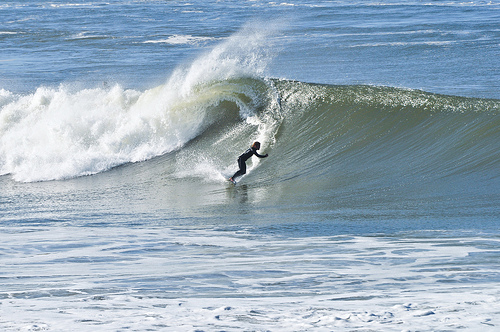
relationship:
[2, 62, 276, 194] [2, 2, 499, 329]
white cap on ocean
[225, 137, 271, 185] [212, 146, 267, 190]
person on surfboard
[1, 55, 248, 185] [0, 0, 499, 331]
foam on ocean water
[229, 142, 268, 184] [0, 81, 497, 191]
person on wave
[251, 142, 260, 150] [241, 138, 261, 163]
head of surfer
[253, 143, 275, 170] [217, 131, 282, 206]
arms of surfer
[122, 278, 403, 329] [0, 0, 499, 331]
ripples of ocean water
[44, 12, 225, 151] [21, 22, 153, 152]
splashing of water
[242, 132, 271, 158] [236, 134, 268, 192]
head of surfer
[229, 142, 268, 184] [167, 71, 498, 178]
person on wave